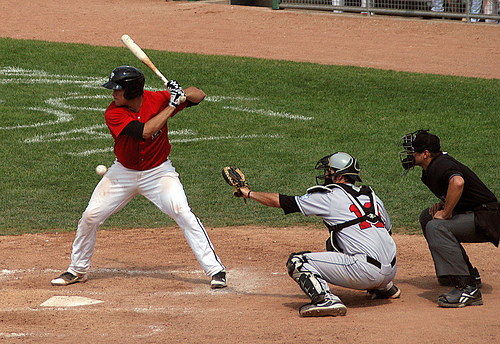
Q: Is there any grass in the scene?
A: Yes, there is grass.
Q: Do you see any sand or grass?
A: Yes, there is grass.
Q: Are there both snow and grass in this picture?
A: No, there is grass but no snow.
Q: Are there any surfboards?
A: No, there are no surfboards.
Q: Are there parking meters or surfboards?
A: No, there are no surfboards or parking meters.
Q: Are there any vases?
A: No, there are no vases.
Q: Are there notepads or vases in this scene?
A: No, there are no vases or notepads.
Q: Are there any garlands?
A: No, there are no garlands.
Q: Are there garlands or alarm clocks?
A: No, there are no garlands or alarm clocks.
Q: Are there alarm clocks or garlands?
A: No, there are no garlands or alarm clocks.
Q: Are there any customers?
A: No, there are no customers.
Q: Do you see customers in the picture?
A: No, there are no customers.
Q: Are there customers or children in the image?
A: No, there are no customers or children.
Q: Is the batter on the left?
A: Yes, the batter is on the left of the image.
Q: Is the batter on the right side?
A: No, the batter is on the left of the image.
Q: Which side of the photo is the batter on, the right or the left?
A: The batter is on the left of the image.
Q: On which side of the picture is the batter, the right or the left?
A: The batter is on the left of the image.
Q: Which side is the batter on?
A: The batter is on the left of the image.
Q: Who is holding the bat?
A: The batter is holding the bat.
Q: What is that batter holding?
A: The batter is holding the bat.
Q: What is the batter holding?
A: The batter is holding the bat.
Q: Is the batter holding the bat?
A: Yes, the batter is holding the bat.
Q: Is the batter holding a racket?
A: No, the batter is holding the bat.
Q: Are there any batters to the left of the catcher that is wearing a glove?
A: Yes, there is a batter to the left of the catcher.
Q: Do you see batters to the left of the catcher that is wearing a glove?
A: Yes, there is a batter to the left of the catcher.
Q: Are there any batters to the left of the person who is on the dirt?
A: Yes, there is a batter to the left of the catcher.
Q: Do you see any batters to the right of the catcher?
A: No, the batter is to the left of the catcher.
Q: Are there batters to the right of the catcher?
A: No, the batter is to the left of the catcher.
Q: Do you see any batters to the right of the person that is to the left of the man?
A: No, the batter is to the left of the catcher.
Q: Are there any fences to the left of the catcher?
A: No, there is a batter to the left of the catcher.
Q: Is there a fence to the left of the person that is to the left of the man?
A: No, there is a batter to the left of the catcher.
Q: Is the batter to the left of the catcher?
A: Yes, the batter is to the left of the catcher.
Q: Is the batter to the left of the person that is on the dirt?
A: Yes, the batter is to the left of the catcher.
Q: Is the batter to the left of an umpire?
A: No, the batter is to the left of the catcher.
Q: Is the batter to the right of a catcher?
A: No, the batter is to the left of a catcher.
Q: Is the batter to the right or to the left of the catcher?
A: The batter is to the left of the catcher.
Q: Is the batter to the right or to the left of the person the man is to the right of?
A: The batter is to the left of the catcher.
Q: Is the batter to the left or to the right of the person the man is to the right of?
A: The batter is to the left of the catcher.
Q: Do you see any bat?
A: Yes, there is a bat.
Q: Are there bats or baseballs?
A: Yes, there is a bat.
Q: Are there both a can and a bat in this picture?
A: No, there is a bat but no cans.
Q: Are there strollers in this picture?
A: No, there are no strollers.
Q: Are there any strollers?
A: No, there are no strollers.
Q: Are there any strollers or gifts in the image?
A: No, there are no strollers or gifts.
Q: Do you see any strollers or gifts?
A: No, there are no strollers or gifts.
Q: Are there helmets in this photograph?
A: Yes, there is a helmet.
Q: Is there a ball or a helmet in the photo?
A: Yes, there is a helmet.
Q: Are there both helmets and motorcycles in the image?
A: No, there is a helmet but no motorcycles.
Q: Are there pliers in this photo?
A: No, there are no pliers.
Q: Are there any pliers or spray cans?
A: No, there are no pliers or spray cans.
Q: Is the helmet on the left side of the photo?
A: Yes, the helmet is on the left of the image.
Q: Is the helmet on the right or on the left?
A: The helmet is on the left of the image.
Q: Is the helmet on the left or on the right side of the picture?
A: The helmet is on the left of the image.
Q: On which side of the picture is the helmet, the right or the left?
A: The helmet is on the left of the image.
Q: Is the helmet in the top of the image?
A: Yes, the helmet is in the top of the image.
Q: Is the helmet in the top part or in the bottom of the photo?
A: The helmet is in the top of the image.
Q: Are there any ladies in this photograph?
A: No, there are no ladies.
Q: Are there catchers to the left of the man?
A: Yes, there is a catcher to the left of the man.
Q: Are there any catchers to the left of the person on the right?
A: Yes, there is a catcher to the left of the man.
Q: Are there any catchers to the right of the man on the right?
A: No, the catcher is to the left of the man.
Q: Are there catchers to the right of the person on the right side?
A: No, the catcher is to the left of the man.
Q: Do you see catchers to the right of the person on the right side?
A: No, the catcher is to the left of the man.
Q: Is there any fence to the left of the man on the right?
A: No, there is a catcher to the left of the man.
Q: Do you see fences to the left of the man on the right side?
A: No, there is a catcher to the left of the man.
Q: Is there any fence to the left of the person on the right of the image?
A: No, there is a catcher to the left of the man.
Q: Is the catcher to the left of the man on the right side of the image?
A: Yes, the catcher is to the left of the man.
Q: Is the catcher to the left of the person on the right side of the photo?
A: Yes, the catcher is to the left of the man.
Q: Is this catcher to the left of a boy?
A: No, the catcher is to the left of the man.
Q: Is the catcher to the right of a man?
A: No, the catcher is to the left of a man.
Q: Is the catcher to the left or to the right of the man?
A: The catcher is to the left of the man.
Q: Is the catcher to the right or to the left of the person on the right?
A: The catcher is to the left of the man.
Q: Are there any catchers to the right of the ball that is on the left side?
A: Yes, there is a catcher to the right of the ball.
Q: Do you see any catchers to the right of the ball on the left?
A: Yes, there is a catcher to the right of the ball.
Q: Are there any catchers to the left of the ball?
A: No, the catcher is to the right of the ball.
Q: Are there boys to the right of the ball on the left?
A: No, there is a catcher to the right of the ball.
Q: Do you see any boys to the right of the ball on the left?
A: No, there is a catcher to the right of the ball.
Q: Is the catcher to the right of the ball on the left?
A: Yes, the catcher is to the right of the ball.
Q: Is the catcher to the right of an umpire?
A: No, the catcher is to the right of the ball.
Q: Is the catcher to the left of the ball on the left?
A: No, the catcher is to the right of the ball.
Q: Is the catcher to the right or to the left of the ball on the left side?
A: The catcher is to the right of the ball.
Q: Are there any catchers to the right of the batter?
A: Yes, there is a catcher to the right of the batter.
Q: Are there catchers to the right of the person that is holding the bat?
A: Yes, there is a catcher to the right of the batter.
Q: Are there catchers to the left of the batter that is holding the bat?
A: No, the catcher is to the right of the batter.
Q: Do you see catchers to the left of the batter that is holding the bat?
A: No, the catcher is to the right of the batter.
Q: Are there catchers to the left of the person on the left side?
A: No, the catcher is to the right of the batter.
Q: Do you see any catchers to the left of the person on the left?
A: No, the catcher is to the right of the batter.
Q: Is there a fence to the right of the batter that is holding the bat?
A: No, there is a catcher to the right of the batter.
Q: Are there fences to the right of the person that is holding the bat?
A: No, there is a catcher to the right of the batter.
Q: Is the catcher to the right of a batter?
A: Yes, the catcher is to the right of a batter.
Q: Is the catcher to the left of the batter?
A: No, the catcher is to the right of the batter.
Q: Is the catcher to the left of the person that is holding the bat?
A: No, the catcher is to the right of the batter.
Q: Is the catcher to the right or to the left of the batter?
A: The catcher is to the right of the batter.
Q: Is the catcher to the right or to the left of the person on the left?
A: The catcher is to the right of the batter.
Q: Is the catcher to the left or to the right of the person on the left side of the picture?
A: The catcher is to the right of the batter.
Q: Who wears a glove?
A: The catcher wears a glove.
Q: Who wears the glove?
A: The catcher wears a glove.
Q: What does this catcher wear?
A: The catcher wears a glove.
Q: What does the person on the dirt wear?
A: The catcher wears a glove.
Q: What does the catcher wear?
A: The catcher wears a glove.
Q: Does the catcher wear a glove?
A: Yes, the catcher wears a glove.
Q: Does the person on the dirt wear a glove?
A: Yes, the catcher wears a glove.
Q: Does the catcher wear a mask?
A: No, the catcher wears a glove.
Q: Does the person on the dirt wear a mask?
A: No, the catcher wears a glove.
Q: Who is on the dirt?
A: The catcher is on the dirt.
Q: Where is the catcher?
A: The catcher is on the dirt.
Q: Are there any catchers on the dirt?
A: Yes, there is a catcher on the dirt.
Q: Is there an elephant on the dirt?
A: No, there is a catcher on the dirt.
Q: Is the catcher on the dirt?
A: Yes, the catcher is on the dirt.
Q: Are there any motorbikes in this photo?
A: No, there are no motorbikes.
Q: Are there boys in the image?
A: No, there are no boys.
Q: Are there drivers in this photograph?
A: No, there are no drivers.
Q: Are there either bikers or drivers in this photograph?
A: No, there are no drivers or bikers.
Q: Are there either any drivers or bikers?
A: No, there are no drivers or bikers.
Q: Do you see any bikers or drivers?
A: No, there are no drivers or bikers.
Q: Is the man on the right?
A: Yes, the man is on the right of the image.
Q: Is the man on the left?
A: No, the man is on the right of the image.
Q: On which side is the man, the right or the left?
A: The man is on the right of the image.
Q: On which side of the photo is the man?
A: The man is on the right of the image.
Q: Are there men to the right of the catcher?
A: Yes, there is a man to the right of the catcher.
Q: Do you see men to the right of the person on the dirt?
A: Yes, there is a man to the right of the catcher.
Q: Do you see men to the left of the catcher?
A: No, the man is to the right of the catcher.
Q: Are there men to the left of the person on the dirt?
A: No, the man is to the right of the catcher.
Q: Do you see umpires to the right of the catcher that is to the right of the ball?
A: No, there is a man to the right of the catcher.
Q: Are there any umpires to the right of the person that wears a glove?
A: No, there is a man to the right of the catcher.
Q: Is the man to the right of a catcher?
A: Yes, the man is to the right of a catcher.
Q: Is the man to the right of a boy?
A: No, the man is to the right of a catcher.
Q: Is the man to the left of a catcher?
A: No, the man is to the right of a catcher.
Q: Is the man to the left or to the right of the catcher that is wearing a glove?
A: The man is to the right of the catcher.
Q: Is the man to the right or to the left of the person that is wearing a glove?
A: The man is to the right of the catcher.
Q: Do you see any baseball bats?
A: Yes, there is a baseball bat.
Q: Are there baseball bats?
A: Yes, there is a baseball bat.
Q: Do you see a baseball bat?
A: Yes, there is a baseball bat.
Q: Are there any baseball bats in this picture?
A: Yes, there is a baseball bat.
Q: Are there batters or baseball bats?
A: Yes, there is a baseball bat.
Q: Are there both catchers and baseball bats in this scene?
A: Yes, there are both a baseball bat and a catcher.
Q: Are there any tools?
A: No, there are no tools.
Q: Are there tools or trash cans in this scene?
A: No, there are no tools or trash cans.